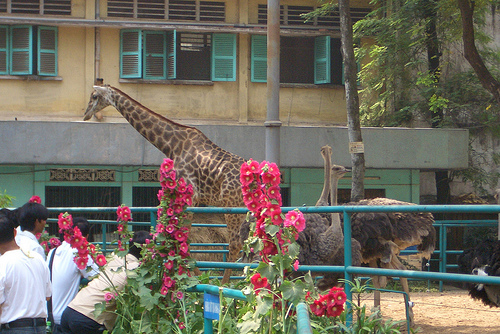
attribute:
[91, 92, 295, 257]
giraffe — tall, brown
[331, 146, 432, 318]
ostrich — brown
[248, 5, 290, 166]
pole — metal, grey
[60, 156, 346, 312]
flowers — pink, pretty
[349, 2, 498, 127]
leaves — green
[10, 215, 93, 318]
shirts — white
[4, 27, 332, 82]
shutters — blue, teal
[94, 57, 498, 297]
animals — in zoo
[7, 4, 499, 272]
buildings — tan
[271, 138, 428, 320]
ostriches — big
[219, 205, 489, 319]
fence — blue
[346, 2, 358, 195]
trunk — grey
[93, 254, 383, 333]
leaves — green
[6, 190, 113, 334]
men — grouped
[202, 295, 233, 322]
sign — blue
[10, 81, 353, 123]
wall — dirty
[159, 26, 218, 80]
windows — open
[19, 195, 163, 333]
people — watching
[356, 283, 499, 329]
ground — sandy